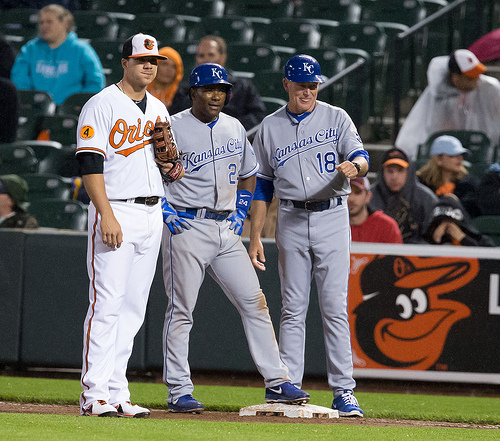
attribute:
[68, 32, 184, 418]
baseball player — white, first base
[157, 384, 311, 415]
shoes — blue, nike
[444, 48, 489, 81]
hat — orange, black, white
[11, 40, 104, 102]
hoodie — blue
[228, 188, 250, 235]
glove — blue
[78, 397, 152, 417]
shoes — white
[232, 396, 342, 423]
base — first base, white, dirty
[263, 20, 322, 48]
chair — empty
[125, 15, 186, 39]
chair — empty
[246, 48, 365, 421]
coach — first base, giving advice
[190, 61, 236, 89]
helmet — batter's, blue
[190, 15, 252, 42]
seat — empty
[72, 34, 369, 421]
players — opposing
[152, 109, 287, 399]
uniform — grey, blue, white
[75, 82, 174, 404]
uniform — orange